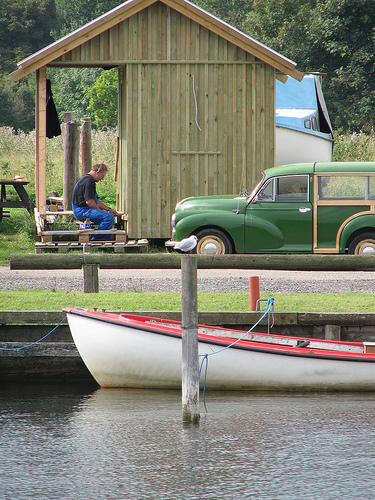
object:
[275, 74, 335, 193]
boat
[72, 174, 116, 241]
overalls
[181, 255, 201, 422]
post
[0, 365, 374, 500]
water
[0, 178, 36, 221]
picnic table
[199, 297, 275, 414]
blue rope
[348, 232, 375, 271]
wheel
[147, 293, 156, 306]
grass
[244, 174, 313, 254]
door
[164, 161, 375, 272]
car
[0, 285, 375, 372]
shore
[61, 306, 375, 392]
boat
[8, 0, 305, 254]
building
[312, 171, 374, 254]
wood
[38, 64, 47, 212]
post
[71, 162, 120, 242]
carpenter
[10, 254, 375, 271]
rail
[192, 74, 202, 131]
cord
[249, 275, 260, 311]
pole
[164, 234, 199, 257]
bird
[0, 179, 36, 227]
bench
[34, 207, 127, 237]
bench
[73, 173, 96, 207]
shirt